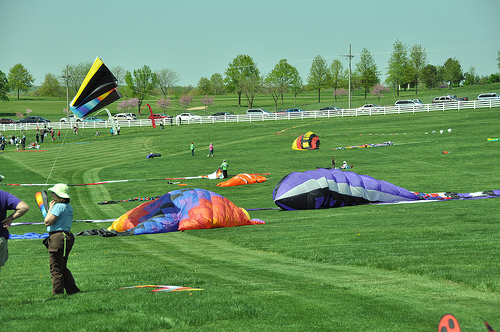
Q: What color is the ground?
A: Green.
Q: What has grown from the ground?
A: Grass and trees.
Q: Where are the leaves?
A: On the tree.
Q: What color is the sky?
A: Blue.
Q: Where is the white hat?
A: On the woman's head.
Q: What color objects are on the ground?
A: Kites.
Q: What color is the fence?
A: White.